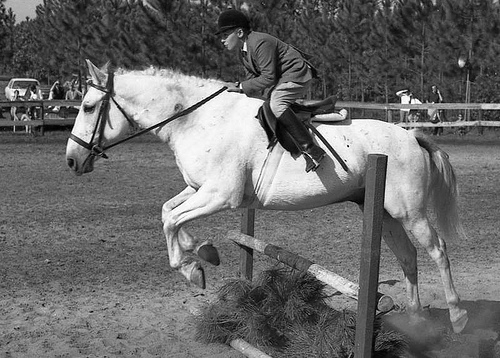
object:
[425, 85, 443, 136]
people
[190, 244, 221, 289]
hooves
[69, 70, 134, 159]
halter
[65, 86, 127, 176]
face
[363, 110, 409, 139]
ground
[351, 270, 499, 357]
dust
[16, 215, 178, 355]
tracks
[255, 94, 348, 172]
saddle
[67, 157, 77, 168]
nostril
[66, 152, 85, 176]
snout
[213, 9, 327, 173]
jockey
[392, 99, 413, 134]
ground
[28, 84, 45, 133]
people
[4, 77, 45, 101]
car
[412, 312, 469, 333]
hooves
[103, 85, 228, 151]
bridle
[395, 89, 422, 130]
people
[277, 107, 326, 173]
boot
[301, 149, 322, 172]
stirrup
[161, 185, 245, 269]
legs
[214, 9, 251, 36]
helmet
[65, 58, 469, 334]
horse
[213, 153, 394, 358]
fence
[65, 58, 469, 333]
jump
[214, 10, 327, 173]
girl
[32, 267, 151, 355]
dirt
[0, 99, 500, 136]
fence